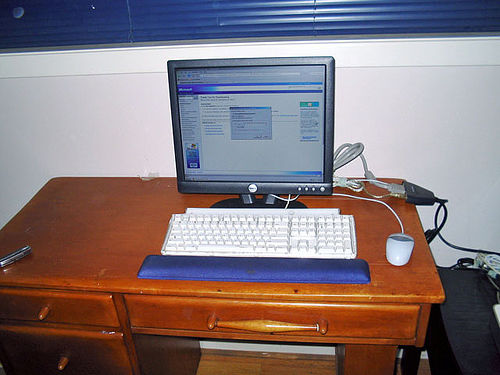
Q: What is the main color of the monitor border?
A: Black.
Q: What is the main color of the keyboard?
A: White.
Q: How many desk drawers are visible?
A: Three.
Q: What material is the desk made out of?
A: Wood.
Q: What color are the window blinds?
A: Blue.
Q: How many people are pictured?
A: None.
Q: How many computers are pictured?
A: One.